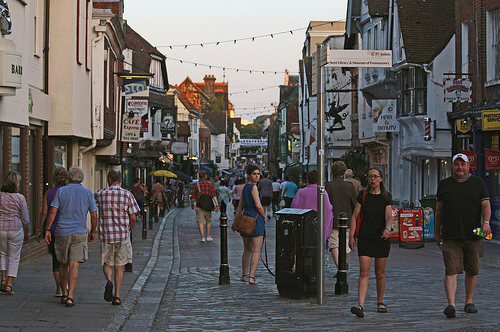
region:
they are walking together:
[6, 163, 141, 295]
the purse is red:
[353, 213, 364, 233]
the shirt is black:
[447, 187, 463, 214]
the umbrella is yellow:
[157, 170, 172, 177]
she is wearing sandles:
[346, 295, 390, 317]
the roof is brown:
[412, 12, 429, 32]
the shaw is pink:
[300, 189, 312, 203]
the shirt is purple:
[48, 189, 55, 199]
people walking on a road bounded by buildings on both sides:
[2, 1, 494, 329]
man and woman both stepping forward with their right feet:
[348, 153, 491, 318]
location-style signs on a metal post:
[314, 40, 393, 307]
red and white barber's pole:
[423, 115, 433, 140]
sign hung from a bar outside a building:
[440, 3, 479, 112]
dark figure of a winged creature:
[323, 82, 363, 133]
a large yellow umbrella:
[146, 167, 178, 180]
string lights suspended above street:
[101, 1, 416, 263]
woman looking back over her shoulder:
[238, 162, 266, 201]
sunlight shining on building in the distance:
[168, 72, 228, 109]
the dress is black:
[354, 195, 404, 266]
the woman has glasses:
[353, 167, 403, 320]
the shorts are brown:
[434, 237, 481, 274]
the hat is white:
[449, 152, 475, 177]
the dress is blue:
[236, 183, 271, 237]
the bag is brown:
[231, 207, 254, 239]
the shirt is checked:
[94, 187, 151, 249]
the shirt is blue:
[51, 185, 98, 232]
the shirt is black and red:
[191, 176, 218, 203]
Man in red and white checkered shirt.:
[90, 160, 147, 309]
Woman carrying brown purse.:
[233, 150, 267, 287]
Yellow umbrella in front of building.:
[150, 165, 176, 187]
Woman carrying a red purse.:
[348, 158, 403, 315]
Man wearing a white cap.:
[431, 148, 492, 318]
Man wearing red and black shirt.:
[191, 169, 220, 243]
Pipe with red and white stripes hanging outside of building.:
[422, 116, 431, 141]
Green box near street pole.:
[270, 208, 320, 304]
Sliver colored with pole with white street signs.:
[295, 42, 395, 308]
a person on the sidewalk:
[437, 143, 497, 260]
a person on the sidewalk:
[340, 161, 380, 298]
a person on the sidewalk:
[338, 146, 353, 231]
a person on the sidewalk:
[310, 164, 340, 231]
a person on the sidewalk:
[242, 161, 244, 271]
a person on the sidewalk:
[202, 157, 232, 239]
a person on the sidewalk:
[75, 156, 150, 263]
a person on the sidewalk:
[33, 148, 93, 271]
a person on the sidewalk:
[5, 171, 37, 253]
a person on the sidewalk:
[190, 169, 219, 254]